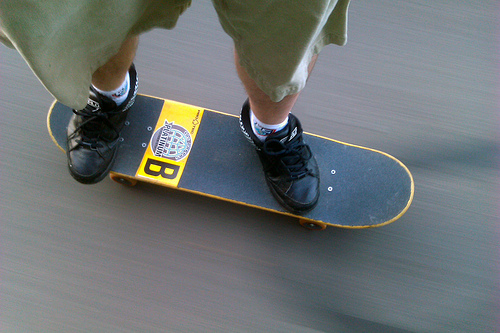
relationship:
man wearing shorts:
[0, 2, 353, 214] [0, 1, 354, 114]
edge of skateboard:
[65, 155, 352, 235] [46, 86, 415, 237]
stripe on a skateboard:
[133, 96, 201, 188] [46, 86, 415, 237]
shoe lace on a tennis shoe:
[262, 122, 314, 187] [237, 96, 329, 215]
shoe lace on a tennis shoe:
[71, 105, 120, 153] [63, 60, 141, 185]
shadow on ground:
[387, 130, 499, 186] [0, 1, 498, 327]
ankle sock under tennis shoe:
[247, 110, 292, 145] [237, 96, 329, 215]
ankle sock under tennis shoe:
[91, 71, 136, 111] [63, 60, 141, 185]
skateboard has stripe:
[46, 86, 415, 237] [133, 96, 201, 188]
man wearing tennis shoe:
[0, 2, 353, 214] [237, 96, 329, 215]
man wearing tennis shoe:
[0, 2, 353, 214] [63, 60, 141, 185]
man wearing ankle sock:
[0, 2, 353, 214] [247, 110, 292, 145]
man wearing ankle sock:
[0, 2, 353, 214] [91, 71, 136, 111]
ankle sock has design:
[247, 110, 292, 145] [252, 121, 275, 141]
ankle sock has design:
[91, 71, 136, 111] [109, 80, 131, 101]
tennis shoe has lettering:
[237, 96, 329, 215] [278, 127, 300, 145]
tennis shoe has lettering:
[63, 60, 141, 185] [83, 96, 100, 111]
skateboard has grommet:
[46, 86, 415, 237] [329, 166, 338, 178]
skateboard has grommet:
[46, 86, 415, 237] [326, 183, 334, 193]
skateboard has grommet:
[46, 86, 415, 237] [148, 126, 154, 131]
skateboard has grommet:
[46, 86, 415, 237] [141, 140, 148, 150]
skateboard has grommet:
[46, 86, 415, 237] [125, 121, 131, 126]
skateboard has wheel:
[46, 86, 415, 237] [105, 168, 140, 190]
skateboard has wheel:
[46, 86, 415, 237] [295, 215, 330, 235]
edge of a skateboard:
[65, 155, 352, 235] [46, 86, 415, 237]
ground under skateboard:
[0, 1, 498, 327] [46, 86, 415, 237]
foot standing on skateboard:
[252, 117, 318, 210] [46, 86, 415, 237]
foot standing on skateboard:
[80, 83, 128, 172] [46, 86, 415, 237]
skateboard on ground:
[46, 86, 415, 237] [0, 1, 498, 327]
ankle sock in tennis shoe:
[247, 110, 292, 145] [237, 96, 329, 215]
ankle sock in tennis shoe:
[91, 71, 136, 111] [63, 60, 141, 185]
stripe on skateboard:
[133, 96, 201, 188] [46, 86, 415, 237]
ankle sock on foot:
[247, 110, 292, 145] [252, 117, 318, 210]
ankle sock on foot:
[91, 71, 136, 111] [80, 83, 128, 172]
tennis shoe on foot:
[237, 96, 329, 215] [252, 117, 318, 210]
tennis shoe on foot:
[63, 60, 141, 185] [80, 83, 128, 172]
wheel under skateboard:
[105, 168, 140, 190] [46, 86, 415, 237]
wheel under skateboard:
[295, 215, 330, 235] [46, 86, 415, 237]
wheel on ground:
[105, 168, 140, 190] [0, 1, 498, 327]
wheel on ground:
[295, 215, 330, 235] [0, 1, 498, 327]